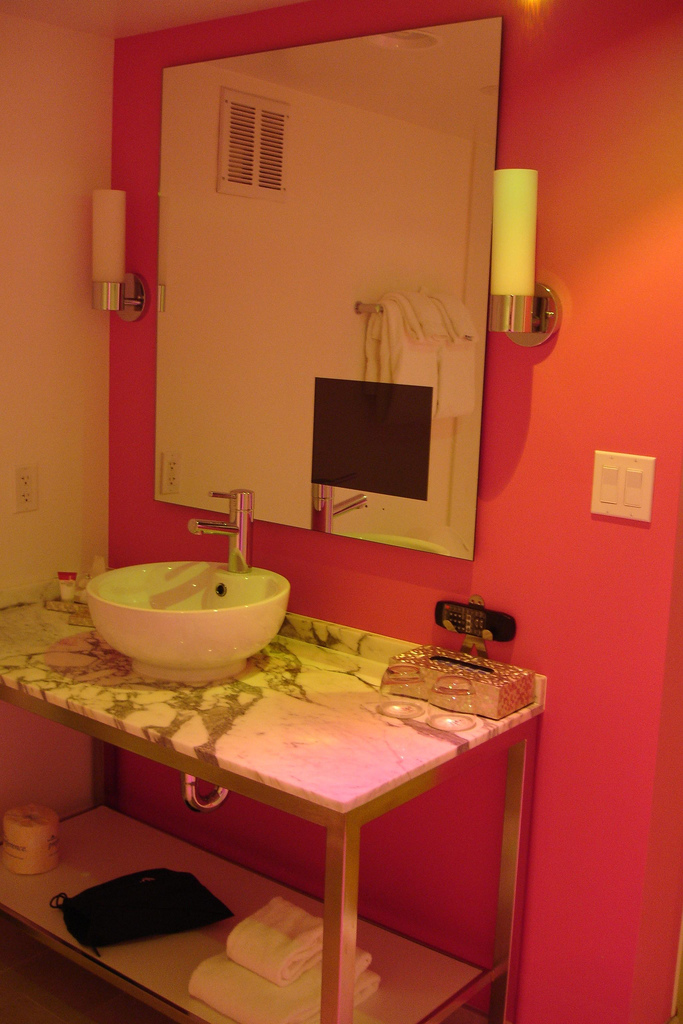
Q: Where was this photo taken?
A: In a hotel bathroom.